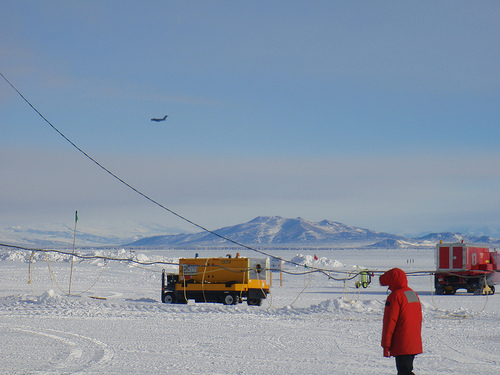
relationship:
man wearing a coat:
[380, 268, 424, 374] [380, 268, 427, 356]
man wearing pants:
[380, 268, 424, 374] [392, 355, 418, 374]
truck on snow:
[161, 254, 273, 306] [2, 244, 499, 372]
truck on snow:
[432, 242, 500, 296] [2, 244, 499, 372]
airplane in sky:
[150, 115, 169, 125] [0, 1, 498, 233]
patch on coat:
[406, 292, 418, 303] [380, 268, 427, 356]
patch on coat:
[384, 302, 392, 306] [380, 268, 427, 356]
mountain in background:
[131, 215, 400, 248] [2, 174, 499, 266]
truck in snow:
[432, 242, 500, 296] [2, 244, 499, 372]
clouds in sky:
[0, 147, 498, 210] [0, 1, 498, 233]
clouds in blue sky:
[0, 147, 498, 210] [0, 1, 498, 233]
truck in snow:
[161, 254, 273, 306] [2, 244, 499, 372]